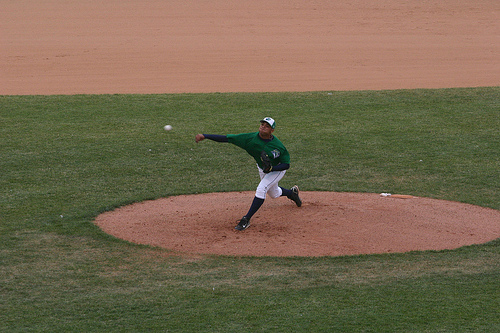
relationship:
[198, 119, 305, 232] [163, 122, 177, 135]
baseball pitcher throwing ball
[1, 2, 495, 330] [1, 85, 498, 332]
baseball field has manicured lawn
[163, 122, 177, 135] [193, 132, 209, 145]
ball leaving hand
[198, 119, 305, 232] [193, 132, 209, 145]
baseball pitcher has hand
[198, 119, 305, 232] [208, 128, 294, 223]
baseball pitcher wearing uniform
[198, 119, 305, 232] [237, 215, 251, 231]
baseball pitcher wearing cleat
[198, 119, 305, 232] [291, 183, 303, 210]
baseball pitcher wearing cleat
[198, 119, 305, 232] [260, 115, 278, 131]
baseball pitcher wearing cap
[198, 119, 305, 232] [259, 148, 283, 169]
baseball pitcher wearing glove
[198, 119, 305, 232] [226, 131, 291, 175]
baseball pitcher wearing top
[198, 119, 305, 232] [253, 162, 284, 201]
baseball pitcher wearing pants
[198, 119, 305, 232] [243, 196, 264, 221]
baseball pitcher wearing sock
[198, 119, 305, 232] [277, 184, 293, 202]
baseball pitcher wearing sock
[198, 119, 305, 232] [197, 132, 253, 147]
baseball pitcher has arm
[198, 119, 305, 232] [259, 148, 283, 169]
baseball pitcher holding glove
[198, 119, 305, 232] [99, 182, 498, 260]
baseball pitcher standing on pitcher mound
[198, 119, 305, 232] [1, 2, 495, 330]
baseball pitcher standing on baseball field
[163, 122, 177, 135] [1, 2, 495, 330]
ball flying over baseball field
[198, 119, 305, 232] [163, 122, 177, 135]
baseball pitcher pitching ball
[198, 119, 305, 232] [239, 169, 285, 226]
baseball pitcher has leg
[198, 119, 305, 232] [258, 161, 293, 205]
baseball pitcher has leg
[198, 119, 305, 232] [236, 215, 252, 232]
baseball pitcher has foot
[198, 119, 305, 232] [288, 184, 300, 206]
baseball pitcher has foot